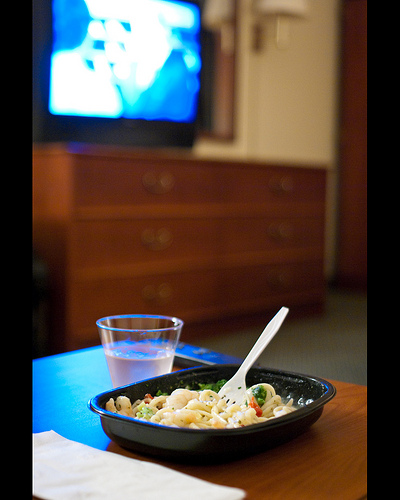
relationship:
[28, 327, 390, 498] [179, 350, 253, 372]
part a table part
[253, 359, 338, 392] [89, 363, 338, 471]
edge of black bowl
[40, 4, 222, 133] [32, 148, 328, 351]
television on dresser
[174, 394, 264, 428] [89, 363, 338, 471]
noodles in black bowl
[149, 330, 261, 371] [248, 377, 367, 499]
remote on brown table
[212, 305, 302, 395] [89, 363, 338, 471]
fork in pasta in black bowl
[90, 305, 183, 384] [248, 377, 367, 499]
cup in brown table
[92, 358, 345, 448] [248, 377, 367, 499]
food on brown table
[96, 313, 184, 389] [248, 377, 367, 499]
drink on brown table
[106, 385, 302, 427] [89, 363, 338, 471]
food in black bowl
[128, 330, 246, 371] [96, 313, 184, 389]
remote control beside drink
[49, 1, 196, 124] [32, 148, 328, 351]
television on dresser